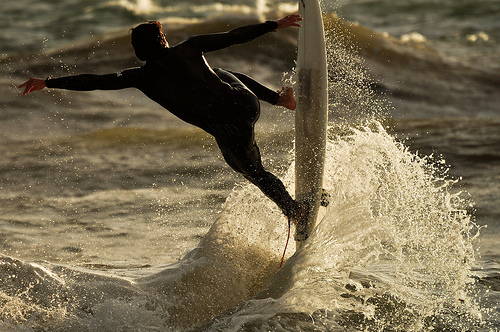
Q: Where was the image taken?
A: It was taken at the ocean.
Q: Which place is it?
A: It is an ocean.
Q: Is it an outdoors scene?
A: Yes, it is outdoors.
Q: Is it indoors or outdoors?
A: It is outdoors.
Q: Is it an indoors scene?
A: No, it is outdoors.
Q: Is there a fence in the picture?
A: No, there are no fences.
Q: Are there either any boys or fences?
A: No, there are no fences or boys.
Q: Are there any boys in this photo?
A: No, there are no boys.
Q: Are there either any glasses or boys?
A: No, there are no boys or glasses.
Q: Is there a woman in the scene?
A: No, there are no women.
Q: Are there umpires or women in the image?
A: No, there are no women or umpires.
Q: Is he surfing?
A: Yes, the man is surfing.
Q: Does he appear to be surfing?
A: Yes, the man is surfing.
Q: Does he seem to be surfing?
A: Yes, the man is surfing.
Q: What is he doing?
A: The man is surfing.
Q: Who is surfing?
A: The man is surfing.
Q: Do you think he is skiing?
A: No, the man is surfing.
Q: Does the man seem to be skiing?
A: No, the man is surfing.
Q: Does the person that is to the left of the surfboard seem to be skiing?
A: No, the man is surfing.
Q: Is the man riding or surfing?
A: The man is surfing.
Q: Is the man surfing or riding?
A: The man is surfing.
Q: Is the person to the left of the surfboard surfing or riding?
A: The man is surfing.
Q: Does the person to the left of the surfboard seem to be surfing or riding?
A: The man is surfing.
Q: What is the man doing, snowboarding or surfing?
A: The man is surfing.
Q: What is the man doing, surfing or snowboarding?
A: The man is surfing.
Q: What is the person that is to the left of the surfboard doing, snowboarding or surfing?
A: The man is surfing.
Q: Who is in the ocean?
A: The man is in the ocean.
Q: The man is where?
A: The man is in the ocean.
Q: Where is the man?
A: The man is in the ocean.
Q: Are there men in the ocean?
A: Yes, there is a man in the ocean.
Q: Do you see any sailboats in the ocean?
A: No, there is a man in the ocean.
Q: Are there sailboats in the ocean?
A: No, there is a man in the ocean.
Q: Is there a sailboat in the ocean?
A: No, there is a man in the ocean.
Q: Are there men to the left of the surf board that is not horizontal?
A: Yes, there is a man to the left of the surf board.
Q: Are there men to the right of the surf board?
A: No, the man is to the left of the surf board.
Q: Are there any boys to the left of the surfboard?
A: No, there is a man to the left of the surfboard.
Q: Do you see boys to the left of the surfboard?
A: No, there is a man to the left of the surfboard.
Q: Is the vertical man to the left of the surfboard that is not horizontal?
A: Yes, the man is to the left of the surfboard.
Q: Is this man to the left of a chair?
A: No, the man is to the left of the surfboard.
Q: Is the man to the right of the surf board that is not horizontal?
A: No, the man is to the left of the surfboard.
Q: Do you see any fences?
A: No, there are no fences.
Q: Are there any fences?
A: No, there are no fences.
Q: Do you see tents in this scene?
A: No, there are no tents.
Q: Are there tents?
A: No, there are no tents.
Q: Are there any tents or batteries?
A: No, there are no tents or batteries.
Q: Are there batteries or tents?
A: No, there are no tents or batteries.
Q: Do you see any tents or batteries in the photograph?
A: No, there are no tents or batteries.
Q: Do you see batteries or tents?
A: No, there are no tents or batteries.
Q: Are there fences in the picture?
A: No, there are no fences.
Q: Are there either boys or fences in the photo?
A: No, there are no fences or boys.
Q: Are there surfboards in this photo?
A: Yes, there is a surfboard.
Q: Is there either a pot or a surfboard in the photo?
A: Yes, there is a surfboard.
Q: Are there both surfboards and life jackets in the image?
A: No, there is a surfboard but no life jackets.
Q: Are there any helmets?
A: No, there are no helmets.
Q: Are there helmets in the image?
A: No, there are no helmets.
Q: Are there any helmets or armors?
A: No, there are no helmets or armors.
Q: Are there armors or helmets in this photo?
A: No, there are no helmets or armors.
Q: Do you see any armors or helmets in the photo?
A: No, there are no helmets or armors.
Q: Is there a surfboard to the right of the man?
A: Yes, there is a surfboard to the right of the man.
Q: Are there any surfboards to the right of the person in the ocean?
A: Yes, there is a surfboard to the right of the man.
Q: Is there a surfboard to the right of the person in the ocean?
A: Yes, there is a surfboard to the right of the man.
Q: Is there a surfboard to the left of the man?
A: No, the surfboard is to the right of the man.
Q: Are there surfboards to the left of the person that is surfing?
A: No, the surfboard is to the right of the man.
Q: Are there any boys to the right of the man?
A: No, there is a surfboard to the right of the man.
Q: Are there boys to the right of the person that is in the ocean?
A: No, there is a surfboard to the right of the man.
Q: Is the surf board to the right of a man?
A: Yes, the surf board is to the right of a man.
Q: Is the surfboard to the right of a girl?
A: No, the surfboard is to the right of a man.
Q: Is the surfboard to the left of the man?
A: No, the surfboard is to the right of the man.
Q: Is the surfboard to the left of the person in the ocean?
A: No, the surfboard is to the right of the man.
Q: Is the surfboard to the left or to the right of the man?
A: The surfboard is to the right of the man.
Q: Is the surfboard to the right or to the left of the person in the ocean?
A: The surfboard is to the right of the man.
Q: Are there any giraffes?
A: No, there are no giraffes.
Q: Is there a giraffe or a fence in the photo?
A: No, there are no giraffes or fences.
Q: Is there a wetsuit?
A: Yes, there is a wetsuit.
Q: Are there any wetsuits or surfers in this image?
A: Yes, there is a wetsuit.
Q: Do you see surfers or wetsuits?
A: Yes, there is a wetsuit.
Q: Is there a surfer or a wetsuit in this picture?
A: Yes, there is a wetsuit.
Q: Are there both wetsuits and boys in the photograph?
A: No, there is a wetsuit but no boys.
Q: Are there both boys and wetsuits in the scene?
A: No, there is a wetsuit but no boys.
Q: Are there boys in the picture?
A: No, there are no boys.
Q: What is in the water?
A: The wetsuit is in the water.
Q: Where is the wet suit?
A: The wet suit is in the water.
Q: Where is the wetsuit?
A: The wet suit is in the water.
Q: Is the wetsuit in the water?
A: Yes, the wetsuit is in the water.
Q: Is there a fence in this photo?
A: No, there are no fences.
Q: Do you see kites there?
A: No, there are no kites.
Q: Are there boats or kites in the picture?
A: No, there are no kites or boats.